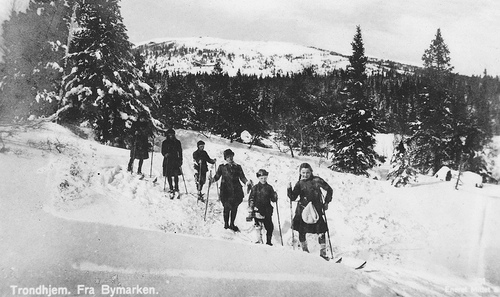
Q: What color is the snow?
A: White.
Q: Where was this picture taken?
A: Outside on mountain.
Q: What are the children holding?
A: Ski Poles.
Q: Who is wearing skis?
A: Children.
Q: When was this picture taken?
A: During the day.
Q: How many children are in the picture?
A: Six.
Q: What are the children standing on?
A: Skis.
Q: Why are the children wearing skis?
A: To go skiing.